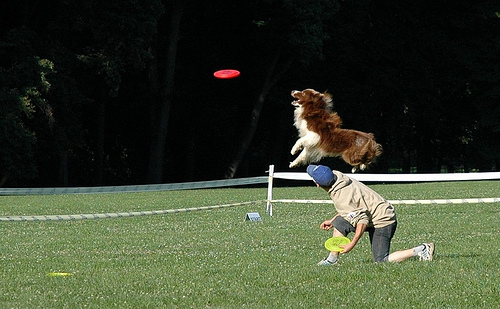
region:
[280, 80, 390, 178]
A white and brown furry dog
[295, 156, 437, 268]
A boy is kneeling down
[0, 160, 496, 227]
A long white fence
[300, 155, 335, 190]
A baseball cap is blue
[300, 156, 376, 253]
A boy is holding a frisbee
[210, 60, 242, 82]
A red frisbee in the air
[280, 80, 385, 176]
A dog is jumping in the air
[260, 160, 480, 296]
A boy is on the grass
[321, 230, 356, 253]
A yellow round frisbee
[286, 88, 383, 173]
Brown and white dog.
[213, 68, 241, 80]
A red colored frisbee.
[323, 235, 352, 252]
A yellow colored frisbee.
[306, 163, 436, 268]
A man kneeling down.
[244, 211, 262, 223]
A white folded placard.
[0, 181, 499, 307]
A large grassy area.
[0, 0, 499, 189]
A dark colored background.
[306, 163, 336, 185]
A blue colored hat.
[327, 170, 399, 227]
A tan colored jacket.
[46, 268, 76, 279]
A frisbee on the ground.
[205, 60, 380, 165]
dog is trying to catch the frisbee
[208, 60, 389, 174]
dog is trying to catch the frisbee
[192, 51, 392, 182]
dog is trying to catch the frisbee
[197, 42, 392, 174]
dog is trying to catch the frisbee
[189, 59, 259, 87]
the frisbee is red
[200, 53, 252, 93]
the frisbee is red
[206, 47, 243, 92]
the frisbee is red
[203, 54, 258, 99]
the frisbee is red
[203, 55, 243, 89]
the frisbee is red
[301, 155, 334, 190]
Blue hat on person's head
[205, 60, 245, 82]
A frisbee is in the air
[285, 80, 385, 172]
A brown and white dog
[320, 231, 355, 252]
A yellow and round frisbee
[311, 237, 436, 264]
A pair of sneakers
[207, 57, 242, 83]
Frisbee is round and red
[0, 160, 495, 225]
A white fence behind the person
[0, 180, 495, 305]
Green grass on the ground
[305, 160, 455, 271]
a person kneeling on the grass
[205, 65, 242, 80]
a red frisbee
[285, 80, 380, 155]
a dog jumping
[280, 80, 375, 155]
a brown and white dog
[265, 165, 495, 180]
a white fence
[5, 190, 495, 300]
the grass under the dog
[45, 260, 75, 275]
a yellow frisbee on the grass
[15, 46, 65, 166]
a tree behind the fence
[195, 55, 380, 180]
a dog jumping for a frisbee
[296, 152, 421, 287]
a person in a blue hat